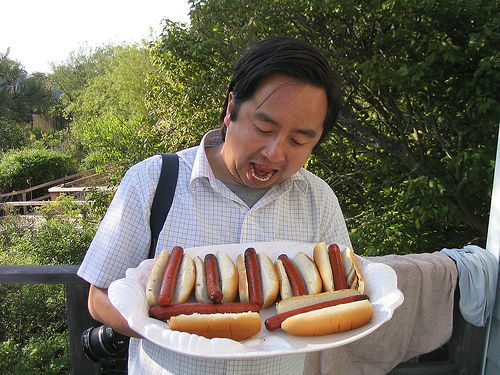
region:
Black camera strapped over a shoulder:
[76, 151, 186, 365]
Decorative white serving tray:
[107, 239, 403, 360]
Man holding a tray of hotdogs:
[76, 34, 402, 372]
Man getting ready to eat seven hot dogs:
[75, 35, 404, 373]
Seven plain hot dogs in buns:
[145, 242, 374, 340]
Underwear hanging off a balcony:
[440, 243, 496, 325]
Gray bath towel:
[298, 248, 458, 373]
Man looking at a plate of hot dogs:
[73, 35, 404, 372]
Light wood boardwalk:
[0, 155, 122, 230]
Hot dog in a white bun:
[262, 285, 372, 337]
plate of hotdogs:
[98, 238, 405, 353]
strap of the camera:
[144, 140, 179, 242]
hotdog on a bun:
[237, 249, 261, 307]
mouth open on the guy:
[247, 153, 283, 190]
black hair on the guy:
[255, 40, 325, 76]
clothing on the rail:
[441, 241, 497, 326]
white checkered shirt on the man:
[193, 195, 212, 219]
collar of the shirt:
[190, 147, 217, 188]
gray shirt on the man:
[230, 181, 250, 196]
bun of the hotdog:
[215, 258, 236, 288]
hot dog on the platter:
[136, 240, 193, 302]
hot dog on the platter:
[182, 245, 232, 308]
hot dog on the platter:
[238, 250, 270, 314]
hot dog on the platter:
[276, 243, 320, 313]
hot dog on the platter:
[321, 243, 366, 298]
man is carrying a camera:
[63, 104, 247, 374]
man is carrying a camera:
[22, 147, 155, 374]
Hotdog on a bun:
[155, 304, 269, 323]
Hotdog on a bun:
[267, 296, 382, 338]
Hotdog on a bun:
[321, 239, 361, 289]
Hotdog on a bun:
[269, 241, 319, 304]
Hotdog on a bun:
[233, 243, 268, 309]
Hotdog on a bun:
[198, 247, 245, 292]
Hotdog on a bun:
[154, 253, 186, 316]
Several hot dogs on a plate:
[99, 229, 424, 368]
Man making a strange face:
[189, 24, 322, 233]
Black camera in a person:
[58, 303, 130, 357]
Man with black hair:
[217, 31, 340, 188]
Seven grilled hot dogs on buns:
[107, 239, 398, 356]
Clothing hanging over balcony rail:
[394, 235, 486, 357]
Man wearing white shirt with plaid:
[168, 36, 348, 238]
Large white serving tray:
[123, 241, 392, 358]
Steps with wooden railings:
[1, 160, 111, 231]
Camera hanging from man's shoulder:
[77, 317, 129, 364]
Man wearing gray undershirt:
[207, 38, 344, 209]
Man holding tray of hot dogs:
[135, 38, 376, 352]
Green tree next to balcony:
[355, 1, 497, 245]